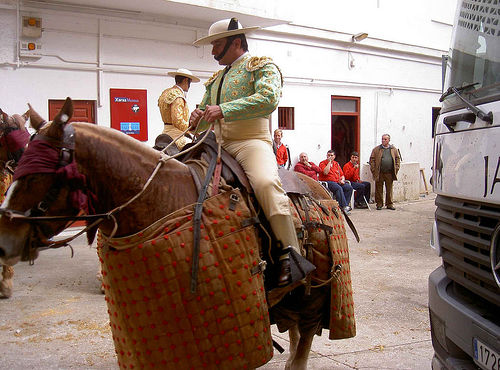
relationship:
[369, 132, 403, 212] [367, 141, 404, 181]
man wearing brown coat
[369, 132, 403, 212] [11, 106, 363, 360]
man on horse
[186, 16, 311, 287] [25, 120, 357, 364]
man on horse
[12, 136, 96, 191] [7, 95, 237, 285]
blindfold on horse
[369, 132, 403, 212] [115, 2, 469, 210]
man sitting near wall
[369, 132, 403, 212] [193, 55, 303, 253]
man wearing outfit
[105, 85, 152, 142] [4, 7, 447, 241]
red sign on wall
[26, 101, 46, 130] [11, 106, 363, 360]
ear are on horse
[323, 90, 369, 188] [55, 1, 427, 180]
door on building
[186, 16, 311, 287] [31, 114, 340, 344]
man riding horse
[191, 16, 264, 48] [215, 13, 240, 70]
hat has black strap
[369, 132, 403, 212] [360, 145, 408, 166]
man wearing brown coat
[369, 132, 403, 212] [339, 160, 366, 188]
man wearing red shirt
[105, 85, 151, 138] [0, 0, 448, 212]
red sign on building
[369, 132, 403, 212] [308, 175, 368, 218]
man sitting on chair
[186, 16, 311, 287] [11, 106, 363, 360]
man on horse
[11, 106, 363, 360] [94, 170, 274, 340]
horse has chest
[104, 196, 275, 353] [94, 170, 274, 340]
cloth tied around chest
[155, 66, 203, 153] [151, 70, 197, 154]
man in jacket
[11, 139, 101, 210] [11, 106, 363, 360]
blindfold on horse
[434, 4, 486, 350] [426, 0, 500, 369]
truck or truck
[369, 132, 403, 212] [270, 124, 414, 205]
man in row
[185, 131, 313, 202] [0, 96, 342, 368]
saddle on horse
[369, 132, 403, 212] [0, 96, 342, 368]
man on horse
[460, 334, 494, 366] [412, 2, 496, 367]
license plate on bus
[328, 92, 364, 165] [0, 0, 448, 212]
doorway of building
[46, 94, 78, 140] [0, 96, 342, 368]
ear on horse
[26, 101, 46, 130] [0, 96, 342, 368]
ear on horse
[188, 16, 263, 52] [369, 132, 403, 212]
hat on man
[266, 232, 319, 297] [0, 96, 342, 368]
stirrup on horse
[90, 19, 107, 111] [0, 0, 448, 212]
pipe on building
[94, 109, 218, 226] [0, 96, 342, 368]
rope on horse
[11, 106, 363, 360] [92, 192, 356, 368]
horse has blanket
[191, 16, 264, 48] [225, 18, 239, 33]
hat with trim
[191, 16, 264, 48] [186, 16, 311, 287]
hat on man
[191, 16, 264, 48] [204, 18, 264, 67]
hat on head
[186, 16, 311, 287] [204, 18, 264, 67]
man has head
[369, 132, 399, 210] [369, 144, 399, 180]
man in a jacket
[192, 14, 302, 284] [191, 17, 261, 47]
man in a hat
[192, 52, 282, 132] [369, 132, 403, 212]
jacket on man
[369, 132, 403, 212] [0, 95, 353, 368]
man looking at horses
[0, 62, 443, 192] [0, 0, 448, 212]
wall on side of building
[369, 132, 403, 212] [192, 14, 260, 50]
man wearing hat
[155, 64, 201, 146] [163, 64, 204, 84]
man wearing hat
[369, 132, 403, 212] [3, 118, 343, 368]
man over horse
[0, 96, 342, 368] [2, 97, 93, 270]
horse has head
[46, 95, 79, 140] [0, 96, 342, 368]
ear of horse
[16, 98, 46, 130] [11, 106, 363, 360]
ear of horse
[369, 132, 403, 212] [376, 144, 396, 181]
man with shirt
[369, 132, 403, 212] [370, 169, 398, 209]
man with pants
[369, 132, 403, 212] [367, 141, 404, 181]
man with brown coat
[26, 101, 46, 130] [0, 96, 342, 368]
ear of horse